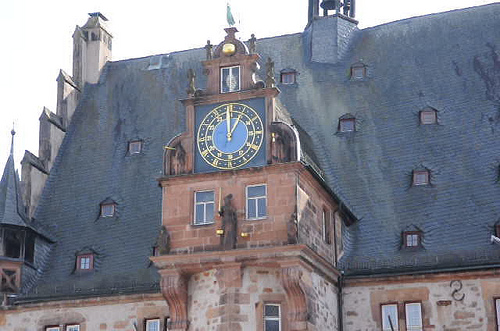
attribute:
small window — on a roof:
[122, 134, 144, 156]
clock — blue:
[192, 101, 272, 168]